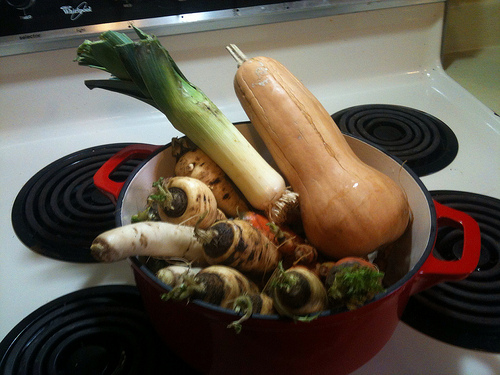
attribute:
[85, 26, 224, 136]
stem — green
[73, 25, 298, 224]
vegetable — green, white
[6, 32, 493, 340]
stove — white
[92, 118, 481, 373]
pot — large, red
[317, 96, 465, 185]
burner — black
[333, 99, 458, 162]
burner — black